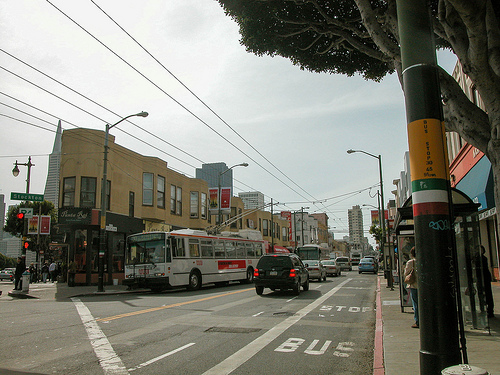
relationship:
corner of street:
[7, 283, 119, 301] [1, 293, 372, 373]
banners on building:
[204, 186, 234, 210] [196, 160, 236, 214]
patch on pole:
[408, 115, 451, 180] [394, 0, 464, 372]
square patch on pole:
[405, 122, 445, 183] [395, 36, 470, 361]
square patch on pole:
[405, 118, 452, 183] [394, 0, 464, 372]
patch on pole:
[408, 115, 451, 180] [384, 0, 470, 371]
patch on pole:
[408, 115, 451, 180] [384, 67, 482, 181]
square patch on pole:
[405, 118, 452, 183] [401, 70, 461, 354]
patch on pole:
[219, 187, 233, 218] [214, 157, 225, 234]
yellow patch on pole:
[98, 215, 107, 230] [96, 111, 150, 292]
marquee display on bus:
[127, 228, 168, 243] [113, 234, 278, 291]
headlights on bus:
[127, 271, 162, 278] [124, 231, 271, 292]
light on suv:
[250, 267, 260, 274] [248, 249, 312, 298]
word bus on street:
[273, 332, 365, 366] [0, 254, 378, 374]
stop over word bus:
[319, 301, 374, 320] [277, 330, 365, 362]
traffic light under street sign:
[13, 212, 32, 241] [8, 186, 53, 196]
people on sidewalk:
[27, 256, 62, 286] [2, 272, 64, 286]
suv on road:
[256, 250, 305, 312] [2, 265, 375, 373]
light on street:
[13, 155, 35, 292] [0, 254, 378, 374]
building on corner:
[40, 115, 212, 290] [8, 283, 119, 298]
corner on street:
[8, 283, 119, 298] [0, 254, 378, 374]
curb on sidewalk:
[370, 271, 387, 372] [384, 290, 498, 373]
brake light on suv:
[281, 266, 299, 282] [241, 247, 329, 307]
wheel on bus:
[186, 268, 202, 295] [70, 193, 397, 348]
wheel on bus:
[242, 262, 258, 280] [124, 231, 271, 292]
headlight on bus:
[156, 273, 164, 275] [125, 228, 265, 289]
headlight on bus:
[125, 273, 132, 275] [125, 228, 265, 289]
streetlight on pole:
[346, 137, 360, 160] [368, 135, 388, 282]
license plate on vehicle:
[268, 267, 278, 278] [248, 253, 310, 293]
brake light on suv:
[288, 268, 297, 278] [256, 251, 310, 296]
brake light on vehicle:
[288, 268, 297, 278] [356, 257, 378, 275]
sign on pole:
[9, 189, 54, 202] [10, 208, 34, 306]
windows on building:
[142, 170, 161, 212] [46, 118, 369, 293]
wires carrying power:
[0, 5, 348, 225] [6, 44, 176, 186]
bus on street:
[124, 231, 271, 292] [0, 254, 378, 374]